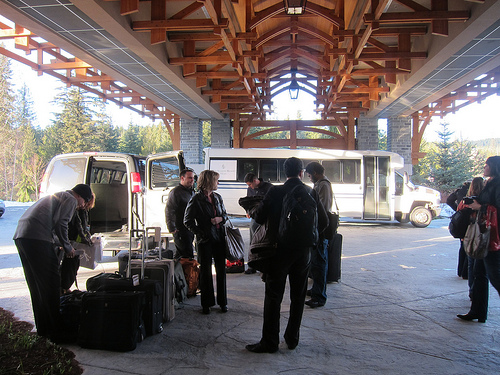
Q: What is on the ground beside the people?
A: Luggage.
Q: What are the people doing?
A: Waiting for rides.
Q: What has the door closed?
A: A bus.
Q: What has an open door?
A: A transport van.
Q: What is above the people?
A: A wood covering.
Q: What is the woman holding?
A: A large bag.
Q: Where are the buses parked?
A: Under the covering.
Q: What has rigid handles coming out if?
A: Some lugage.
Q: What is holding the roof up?
A: Brick columns.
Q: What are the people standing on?
A: Slate paving.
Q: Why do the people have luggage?
A: Going on a trip.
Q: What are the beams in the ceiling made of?
A: Wood.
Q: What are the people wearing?
A: Clothes.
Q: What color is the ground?
A: Grey.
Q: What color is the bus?
A: White.